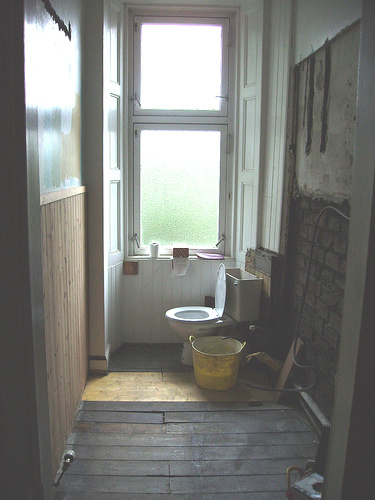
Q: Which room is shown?
A: It is a bathroom.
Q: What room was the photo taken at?
A: It was taken at the bathroom.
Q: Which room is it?
A: It is a bathroom.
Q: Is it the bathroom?
A: Yes, it is the bathroom.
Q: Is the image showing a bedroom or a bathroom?
A: It is showing a bathroom.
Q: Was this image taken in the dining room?
A: No, the picture was taken in the bathroom.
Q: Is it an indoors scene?
A: Yes, it is indoors.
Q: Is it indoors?
A: Yes, it is indoors.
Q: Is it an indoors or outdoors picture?
A: It is indoors.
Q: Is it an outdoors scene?
A: No, it is indoors.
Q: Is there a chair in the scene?
A: No, there are no chairs.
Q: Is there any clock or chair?
A: No, there are no chairs or clocks.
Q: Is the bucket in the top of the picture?
A: No, the bucket is in the bottom of the image.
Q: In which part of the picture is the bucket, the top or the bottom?
A: The bucket is in the bottom of the image.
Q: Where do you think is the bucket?
A: The bucket is on the floor.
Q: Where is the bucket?
A: The bucket is on the floor.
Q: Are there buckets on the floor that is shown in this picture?
A: Yes, there is a bucket on the floor.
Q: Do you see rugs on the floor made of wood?
A: No, there is a bucket on the floor.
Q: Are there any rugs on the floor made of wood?
A: No, there is a bucket on the floor.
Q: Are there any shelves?
A: No, there are no shelves.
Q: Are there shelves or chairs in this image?
A: No, there are no shelves or chairs.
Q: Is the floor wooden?
A: Yes, the floor is wooden.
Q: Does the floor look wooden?
A: Yes, the floor is wooden.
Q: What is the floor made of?
A: The floor is made of wood.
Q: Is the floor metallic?
A: No, the floor is wooden.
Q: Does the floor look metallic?
A: No, the floor is wooden.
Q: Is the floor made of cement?
A: No, the floor is made of wood.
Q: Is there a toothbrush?
A: No, there are no toothbrushes.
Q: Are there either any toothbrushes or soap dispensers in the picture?
A: No, there are no toothbrushes or soap dispensers.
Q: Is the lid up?
A: Yes, the lid is up.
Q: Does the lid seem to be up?
A: Yes, the lid is up.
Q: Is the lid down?
A: No, the lid is up.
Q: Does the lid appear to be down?
A: No, the lid is up.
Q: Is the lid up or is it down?
A: The lid is up.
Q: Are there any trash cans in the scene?
A: No, there are no trash cans.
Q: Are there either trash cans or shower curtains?
A: No, there are no trash cans or shower curtains.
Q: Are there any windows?
A: Yes, there is a window.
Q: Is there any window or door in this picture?
A: Yes, there is a window.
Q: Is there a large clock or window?
A: Yes, there is a large window.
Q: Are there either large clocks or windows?
A: Yes, there is a large window.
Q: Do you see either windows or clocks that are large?
A: Yes, the window is large.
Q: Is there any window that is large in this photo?
A: Yes, there is a large window.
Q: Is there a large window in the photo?
A: Yes, there is a large window.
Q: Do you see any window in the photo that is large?
A: Yes, there is a window that is large.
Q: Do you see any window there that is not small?
A: Yes, there is a large window.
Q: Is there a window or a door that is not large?
A: No, there is a window but it is large.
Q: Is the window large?
A: Yes, the window is large.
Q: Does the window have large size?
A: Yes, the window is large.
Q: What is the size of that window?
A: The window is large.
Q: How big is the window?
A: The window is large.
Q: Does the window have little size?
A: No, the window is large.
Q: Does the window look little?
A: No, the window is large.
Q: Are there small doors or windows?
A: No, there is a window but it is large.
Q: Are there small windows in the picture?
A: No, there is a window but it is large.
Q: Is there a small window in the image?
A: No, there is a window but it is large.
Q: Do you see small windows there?
A: No, there is a window but it is large.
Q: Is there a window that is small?
A: No, there is a window but it is large.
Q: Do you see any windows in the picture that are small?
A: No, there is a window but it is large.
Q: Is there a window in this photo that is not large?
A: No, there is a window but it is large.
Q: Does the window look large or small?
A: The window is large.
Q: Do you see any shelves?
A: No, there are no shelves.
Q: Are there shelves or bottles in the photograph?
A: No, there are no shelves or bottles.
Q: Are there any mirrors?
A: No, there are no mirrors.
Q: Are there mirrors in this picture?
A: No, there are no mirrors.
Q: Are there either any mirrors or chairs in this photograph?
A: No, there are no mirrors or chairs.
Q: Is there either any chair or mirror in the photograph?
A: No, there are no mirrors or chairs.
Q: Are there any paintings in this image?
A: No, there are no paintings.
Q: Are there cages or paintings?
A: No, there are no paintings or cages.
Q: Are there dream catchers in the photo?
A: No, there are no dream catchers.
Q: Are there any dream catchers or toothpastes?
A: No, there are no dream catchers or toothpastes.